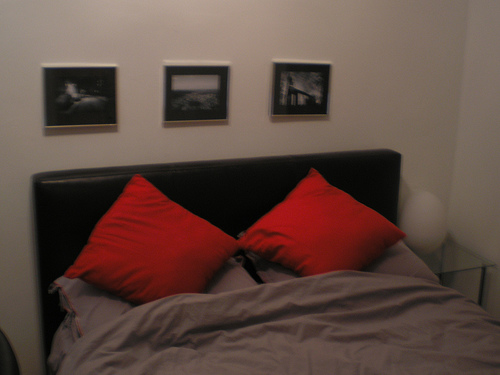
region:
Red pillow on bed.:
[268, 171, 371, 345]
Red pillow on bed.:
[98, 226, 184, 283]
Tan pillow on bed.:
[83, 287, 155, 314]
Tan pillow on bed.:
[254, 250, 400, 276]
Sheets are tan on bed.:
[177, 282, 347, 372]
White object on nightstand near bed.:
[403, 190, 457, 269]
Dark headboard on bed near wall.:
[186, 167, 278, 200]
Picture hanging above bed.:
[251, 45, 350, 147]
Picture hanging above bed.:
[152, 63, 229, 157]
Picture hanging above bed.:
[21, 57, 121, 182]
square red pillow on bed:
[269, 144, 426, 275]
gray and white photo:
[247, 54, 399, 129]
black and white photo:
[147, 57, 247, 129]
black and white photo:
[17, 47, 199, 139]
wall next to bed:
[396, 110, 477, 219]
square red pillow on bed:
[73, 162, 226, 306]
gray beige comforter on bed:
[145, 282, 394, 372]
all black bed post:
[158, 133, 273, 208]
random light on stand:
[391, 180, 468, 268]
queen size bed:
[17, 166, 494, 366]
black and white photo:
[255, 54, 373, 126]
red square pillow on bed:
[250, 158, 379, 296]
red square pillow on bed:
[60, 183, 249, 314]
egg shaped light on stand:
[399, 178, 446, 273]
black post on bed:
[151, 153, 298, 227]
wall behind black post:
[1, 110, 98, 190]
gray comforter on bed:
[190, 288, 447, 370]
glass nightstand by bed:
[425, 248, 492, 298]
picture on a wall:
[259, 53, 339, 126]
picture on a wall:
[151, 57, 240, 130]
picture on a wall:
[33, 60, 123, 140]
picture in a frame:
[30, 60, 125, 135]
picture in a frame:
[152, 55, 233, 135]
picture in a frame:
[261, 53, 337, 127]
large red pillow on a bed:
[57, 165, 244, 315]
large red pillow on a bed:
[232, 162, 412, 287]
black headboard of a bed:
[25, 141, 413, 282]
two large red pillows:
[44, 171, 408, 298]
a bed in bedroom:
[3, 2, 499, 374]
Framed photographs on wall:
[36, 56, 334, 135]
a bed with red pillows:
[30, 145, 497, 372]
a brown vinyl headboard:
[23, 143, 405, 291]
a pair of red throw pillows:
[58, 163, 410, 309]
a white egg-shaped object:
[396, 184, 456, 255]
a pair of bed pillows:
[46, 230, 443, 343]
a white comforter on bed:
[33, 259, 499, 374]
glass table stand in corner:
[410, 235, 499, 305]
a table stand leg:
[474, 262, 489, 308]